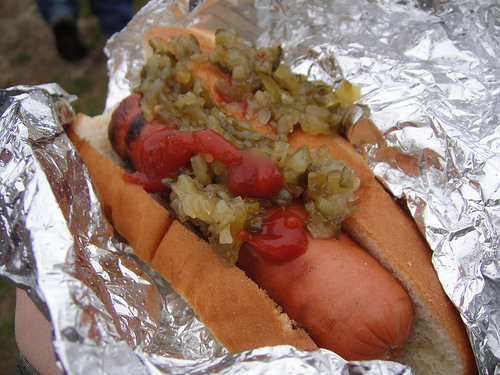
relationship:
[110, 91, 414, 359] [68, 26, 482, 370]
hotdog on bun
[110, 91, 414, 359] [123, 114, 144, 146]
hotdog has burn mark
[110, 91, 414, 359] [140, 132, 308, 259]
hotdog has ketchup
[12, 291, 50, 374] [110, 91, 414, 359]
hand holding hotdog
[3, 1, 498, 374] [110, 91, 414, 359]
foil holding hotdog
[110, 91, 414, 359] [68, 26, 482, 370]
hotdog laying in bun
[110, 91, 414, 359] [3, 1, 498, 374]
hotdog wrapped in foil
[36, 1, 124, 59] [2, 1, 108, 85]
person walking on ground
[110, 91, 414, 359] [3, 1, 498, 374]
hotdog served foil